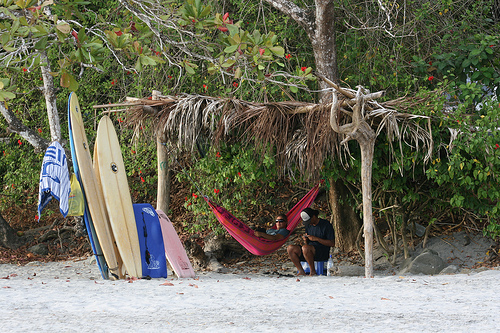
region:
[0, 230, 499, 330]
the sand on the ground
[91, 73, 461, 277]
the shack made of dry leaves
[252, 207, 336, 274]
the people under the shack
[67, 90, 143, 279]
the group of surfboards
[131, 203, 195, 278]
the two boogie boards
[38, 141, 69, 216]
the towel hanging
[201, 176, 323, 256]
the red hammock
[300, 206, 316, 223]
the hat on the man's head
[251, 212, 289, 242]
the man in the hammock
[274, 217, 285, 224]
the sunglasses on the man's face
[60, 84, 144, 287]
surfboards stuck in the sand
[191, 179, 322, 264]
red hammock man is laying in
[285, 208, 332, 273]
man wearing a black and white hat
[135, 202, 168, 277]
blue boogie board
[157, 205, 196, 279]
light pink boogie board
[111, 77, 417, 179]
grass roof over the men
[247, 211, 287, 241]
man in the hammock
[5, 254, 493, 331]
sand the men are on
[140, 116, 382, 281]
two wood poles holding up the roof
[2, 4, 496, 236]
trees behind the two men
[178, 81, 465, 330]
a red hammock hangin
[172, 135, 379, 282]
a red hammock hanging from trees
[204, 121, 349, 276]
a person laying in a hammock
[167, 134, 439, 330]
a person laying in red hammock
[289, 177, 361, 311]
a person wearing a hat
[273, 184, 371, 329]
a person sitting on the beach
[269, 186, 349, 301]
a person sittin gon the sand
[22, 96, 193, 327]
surfboards on the beach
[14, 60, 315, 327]
surfboards on the sand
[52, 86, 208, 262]
surfboard standing up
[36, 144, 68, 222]
a towel hanging on a branch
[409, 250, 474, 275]
some stones to the right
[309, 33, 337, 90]
a thick tree stem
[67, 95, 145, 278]
a couple of surfboards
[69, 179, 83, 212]
looks like a yellow bag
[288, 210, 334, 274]
the man is sitting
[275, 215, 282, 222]
this is a sunglasses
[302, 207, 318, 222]
the head of the man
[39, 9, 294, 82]
many green tree leaves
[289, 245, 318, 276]
the legs of the man